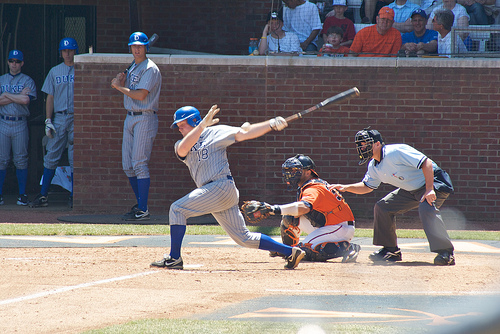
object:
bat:
[268, 86, 360, 129]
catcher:
[241, 151, 361, 266]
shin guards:
[303, 239, 348, 261]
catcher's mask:
[280, 157, 303, 189]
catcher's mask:
[353, 126, 375, 167]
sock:
[170, 221, 187, 260]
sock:
[258, 232, 292, 258]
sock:
[135, 175, 150, 207]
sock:
[40, 163, 56, 195]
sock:
[13, 165, 29, 195]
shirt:
[294, 176, 358, 226]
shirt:
[349, 23, 403, 56]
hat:
[377, 5, 396, 21]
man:
[349, 2, 403, 56]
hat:
[409, 8, 428, 19]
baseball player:
[154, 101, 307, 269]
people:
[248, 10, 301, 56]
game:
[8, 28, 499, 330]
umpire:
[332, 128, 457, 266]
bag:
[434, 167, 457, 194]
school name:
[55, 72, 77, 84]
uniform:
[117, 63, 162, 178]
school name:
[1, 83, 26, 94]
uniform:
[1, 72, 35, 168]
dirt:
[1, 244, 225, 325]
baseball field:
[3, 203, 498, 333]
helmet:
[168, 104, 204, 132]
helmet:
[126, 30, 151, 47]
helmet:
[279, 154, 318, 193]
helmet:
[6, 46, 26, 62]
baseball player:
[110, 29, 165, 222]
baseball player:
[36, 34, 78, 211]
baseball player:
[0, 47, 33, 208]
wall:
[73, 56, 499, 225]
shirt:
[401, 29, 439, 56]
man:
[399, 7, 439, 59]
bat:
[117, 32, 159, 88]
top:
[73, 49, 498, 70]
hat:
[60, 38, 78, 51]